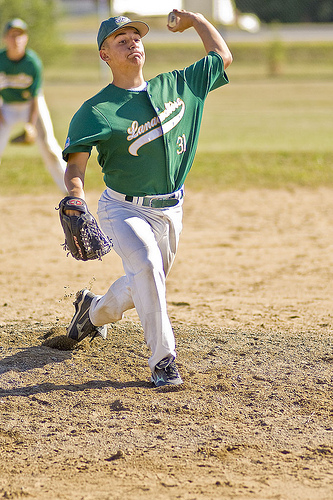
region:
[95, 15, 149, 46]
a green baseball cap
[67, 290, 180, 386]
a pair of white and black baseball cleats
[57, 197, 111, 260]
a black baseball pitcher's glove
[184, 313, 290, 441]
dirt on a baseball field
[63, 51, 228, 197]
a green short sleve baseball jersey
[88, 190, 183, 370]
a pair of white baseball pants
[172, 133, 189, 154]
white thirty one with gold trim on green jersey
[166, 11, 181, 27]
a whtie baseball with red stitching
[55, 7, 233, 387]
a baseball player pitching a ball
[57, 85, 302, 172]
green grass on a baseball outfield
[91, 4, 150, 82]
head of a person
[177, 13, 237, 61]
arm of a person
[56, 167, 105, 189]
elbow of a person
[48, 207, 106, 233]
hand of a person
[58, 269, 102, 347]
feet of a person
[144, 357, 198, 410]
feet of a person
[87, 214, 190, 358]
leg of a person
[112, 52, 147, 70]
mouth of a person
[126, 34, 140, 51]
nose of a person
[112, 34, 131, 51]
eye of a person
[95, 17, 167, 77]
face of the person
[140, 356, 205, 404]
shoe of the person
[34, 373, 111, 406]
shadow on the ground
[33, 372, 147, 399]
shadow of the man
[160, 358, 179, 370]
lace on the shoe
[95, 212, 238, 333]
a man wearing white pant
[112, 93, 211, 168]
name on the shirt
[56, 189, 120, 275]
a man wearing gloves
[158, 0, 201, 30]
a man throwing ball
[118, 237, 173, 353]
leg of a person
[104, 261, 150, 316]
leg of a person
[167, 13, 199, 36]
hand of a person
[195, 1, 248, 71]
arm of a person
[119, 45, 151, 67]
mouth of a person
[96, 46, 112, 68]
ear of a person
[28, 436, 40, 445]
brown dirt on ground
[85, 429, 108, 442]
brown dirt on ground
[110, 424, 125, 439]
brown dirt on ground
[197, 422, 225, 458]
brown dirt on ground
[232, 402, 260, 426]
brown dirt on ground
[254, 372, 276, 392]
brown dirt on ground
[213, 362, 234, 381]
brown dirt on ground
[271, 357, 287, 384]
brown dirt on ground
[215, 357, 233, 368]
brown dirt on ground